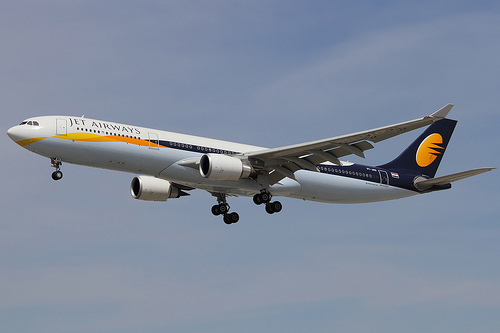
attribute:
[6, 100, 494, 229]
airplane — white, yellow, blue, jet airways, long, commercial, flying, orange, large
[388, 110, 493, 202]
tail — blue, yellow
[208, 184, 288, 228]
landing gear — out, open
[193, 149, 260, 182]
engine — turbo jet engine, white, large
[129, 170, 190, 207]
engine — turbo jet engine, white, large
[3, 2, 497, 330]
sky — cloudy, gray, blue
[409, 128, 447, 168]
logo — yellow, sun, blue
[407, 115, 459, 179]
background — blue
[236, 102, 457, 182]
wing — long, silver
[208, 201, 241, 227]
tire — black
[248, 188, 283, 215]
tire — black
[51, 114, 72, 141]
door — closed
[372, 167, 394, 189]
door — closed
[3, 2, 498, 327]
clouds — fluffly, white